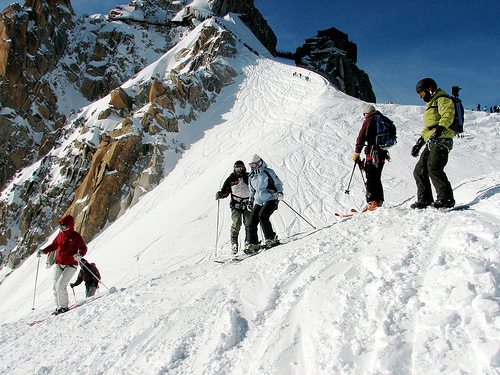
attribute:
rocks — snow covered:
[0, 3, 370, 273]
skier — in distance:
[72, 258, 97, 298]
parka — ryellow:
[420, 88, 455, 141]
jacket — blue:
[247, 175, 272, 192]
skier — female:
[243, 152, 279, 192]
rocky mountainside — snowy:
[1, 0, 240, 287]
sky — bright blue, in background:
[353, 19, 457, 79]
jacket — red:
[38, 226, 88, 266]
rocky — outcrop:
[293, 26, 375, 100]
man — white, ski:
[335, 106, 415, 204]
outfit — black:
[348, 119, 419, 169]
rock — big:
[293, 16, 379, 108]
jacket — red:
[43, 215, 86, 265]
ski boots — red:
[360, 200, 382, 212]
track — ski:
[203, 85, 249, 162]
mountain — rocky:
[4, 12, 359, 180]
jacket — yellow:
[416, 95, 462, 149]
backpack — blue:
[370, 110, 400, 148]